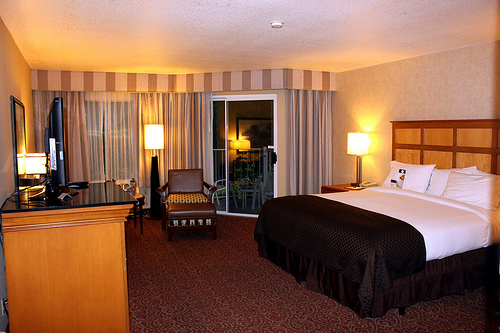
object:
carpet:
[126, 260, 176, 328]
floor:
[450, 314, 497, 329]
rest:
[165, 202, 221, 241]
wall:
[324, 74, 451, 114]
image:
[7, 95, 29, 187]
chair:
[160, 168, 220, 241]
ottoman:
[164, 200, 217, 218]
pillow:
[441, 166, 499, 204]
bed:
[254, 117, 497, 316]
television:
[7, 95, 29, 189]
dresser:
[0, 184, 132, 331]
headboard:
[377, 117, 499, 178]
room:
[1, 0, 498, 332]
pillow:
[388, 155, 435, 192]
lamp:
[143, 122, 169, 220]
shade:
[139, 117, 144, 143]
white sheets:
[415, 208, 485, 263]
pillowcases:
[427, 168, 449, 199]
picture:
[9, 93, 33, 149]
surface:
[6, 176, 140, 206]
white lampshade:
[346, 130, 373, 159]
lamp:
[346, 132, 372, 182]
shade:
[332, 130, 343, 152]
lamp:
[24, 152, 46, 179]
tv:
[39, 92, 71, 191]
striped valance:
[22, 69, 346, 95]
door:
[198, 92, 280, 221]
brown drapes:
[34, 85, 332, 212]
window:
[73, 92, 147, 202]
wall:
[0, 15, 32, 76]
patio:
[212, 96, 272, 213]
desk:
[314, 177, 378, 199]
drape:
[39, 92, 91, 186]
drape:
[139, 92, 198, 207]